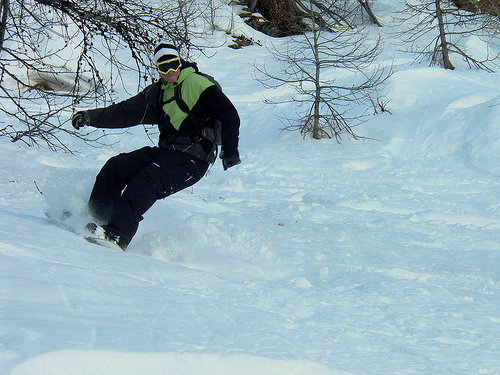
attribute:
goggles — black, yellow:
[156, 58, 188, 75]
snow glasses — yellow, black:
[154, 56, 183, 74]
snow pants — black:
[87, 143, 215, 247]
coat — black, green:
[81, 63, 239, 165]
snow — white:
[4, 144, 495, 373]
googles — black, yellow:
[156, 54, 186, 77]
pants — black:
[86, 142, 208, 249]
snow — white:
[0, 0, 499, 371]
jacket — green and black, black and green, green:
[83, 60, 243, 164]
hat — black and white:
[152, 41, 181, 64]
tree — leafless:
[385, 3, 498, 75]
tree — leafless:
[249, 0, 401, 146]